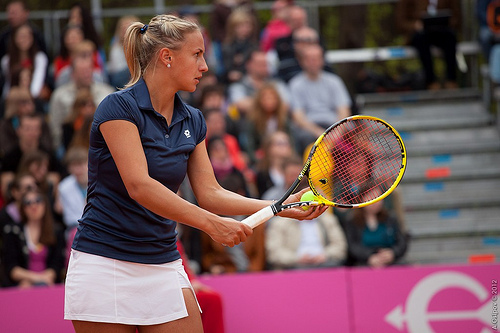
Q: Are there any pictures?
A: No, there are no pictures.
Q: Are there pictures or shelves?
A: No, there are no pictures or shelves.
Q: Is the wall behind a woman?
A: Yes, the wall is behind a woman.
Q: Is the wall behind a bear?
A: No, the wall is behind a woman.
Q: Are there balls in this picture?
A: Yes, there is a ball.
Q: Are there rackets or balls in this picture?
A: Yes, there is a ball.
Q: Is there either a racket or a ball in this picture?
A: Yes, there is a ball.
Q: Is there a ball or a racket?
A: Yes, there is a ball.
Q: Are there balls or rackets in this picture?
A: Yes, there is a ball.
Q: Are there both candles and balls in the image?
A: No, there is a ball but no candles.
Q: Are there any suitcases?
A: No, there are no suitcases.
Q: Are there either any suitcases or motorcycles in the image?
A: No, there are no suitcases or motorcycles.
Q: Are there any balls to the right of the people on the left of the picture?
A: Yes, there is a ball to the right of the people.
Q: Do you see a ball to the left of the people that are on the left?
A: No, the ball is to the right of the people.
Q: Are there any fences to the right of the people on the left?
A: No, there is a ball to the right of the people.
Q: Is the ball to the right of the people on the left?
A: Yes, the ball is to the right of the people.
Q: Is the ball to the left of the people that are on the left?
A: No, the ball is to the right of the people.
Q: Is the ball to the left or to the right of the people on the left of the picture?
A: The ball is to the right of the people.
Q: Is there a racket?
A: Yes, there is a racket.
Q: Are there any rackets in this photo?
A: Yes, there is a racket.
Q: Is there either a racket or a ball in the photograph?
A: Yes, there is a racket.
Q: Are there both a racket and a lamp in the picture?
A: No, there is a racket but no lamps.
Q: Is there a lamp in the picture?
A: No, there are no lamps.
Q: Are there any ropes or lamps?
A: No, there are no lamps or ropes.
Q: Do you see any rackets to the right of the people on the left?
A: Yes, there is a racket to the right of the people.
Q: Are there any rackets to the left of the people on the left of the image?
A: No, the racket is to the right of the people.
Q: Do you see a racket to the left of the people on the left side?
A: No, the racket is to the right of the people.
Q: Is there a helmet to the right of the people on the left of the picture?
A: No, there is a racket to the right of the people.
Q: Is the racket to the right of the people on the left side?
A: Yes, the racket is to the right of the people.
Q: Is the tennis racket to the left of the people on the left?
A: No, the tennis racket is to the right of the people.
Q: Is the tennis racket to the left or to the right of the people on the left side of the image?
A: The tennis racket is to the right of the people.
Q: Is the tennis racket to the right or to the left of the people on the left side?
A: The tennis racket is to the right of the people.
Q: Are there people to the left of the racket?
A: Yes, there are people to the left of the racket.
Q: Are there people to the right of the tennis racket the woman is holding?
A: No, the people are to the left of the tennis racket.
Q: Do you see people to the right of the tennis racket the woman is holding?
A: No, the people are to the left of the tennis racket.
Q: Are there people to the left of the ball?
A: Yes, there are people to the left of the ball.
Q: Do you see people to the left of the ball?
A: Yes, there are people to the left of the ball.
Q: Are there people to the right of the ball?
A: No, the people are to the left of the ball.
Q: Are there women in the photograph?
A: Yes, there is a woman.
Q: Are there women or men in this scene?
A: Yes, there is a woman.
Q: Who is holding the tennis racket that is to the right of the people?
A: The woman is holding the tennis racket.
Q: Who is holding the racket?
A: The woman is holding the tennis racket.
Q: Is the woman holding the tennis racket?
A: Yes, the woman is holding the tennis racket.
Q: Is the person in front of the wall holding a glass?
A: No, the woman is holding the tennis racket.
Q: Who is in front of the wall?
A: The woman is in front of the wall.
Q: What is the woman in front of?
A: The woman is in front of the wall.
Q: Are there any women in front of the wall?
A: Yes, there is a woman in front of the wall.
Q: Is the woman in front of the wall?
A: Yes, the woman is in front of the wall.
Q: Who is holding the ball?
A: The woman is holding the ball.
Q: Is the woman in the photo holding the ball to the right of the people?
A: Yes, the woman is holding the ball.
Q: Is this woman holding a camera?
A: No, the woman is holding the ball.